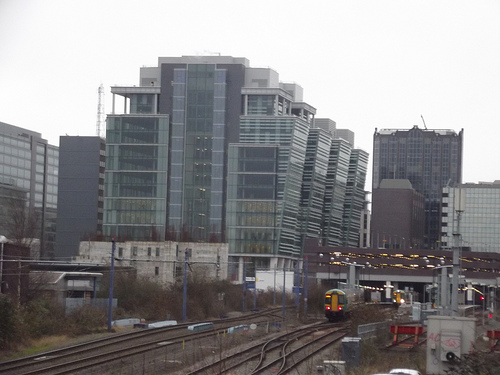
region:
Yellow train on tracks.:
[304, 272, 359, 363]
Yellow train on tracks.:
[384, 278, 438, 355]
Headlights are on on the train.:
[382, 270, 423, 326]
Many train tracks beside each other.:
[166, 317, 241, 369]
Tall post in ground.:
[76, 247, 146, 371]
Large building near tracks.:
[136, 50, 300, 272]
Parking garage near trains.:
[315, 231, 497, 293]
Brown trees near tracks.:
[41, 275, 276, 348]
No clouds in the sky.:
[328, 40, 496, 135]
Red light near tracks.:
[473, 286, 483, 301]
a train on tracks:
[315, 283, 378, 323]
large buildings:
[60, 57, 374, 259]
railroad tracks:
[43, 316, 330, 373]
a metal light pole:
[103, 236, 124, 326]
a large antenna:
[94, 73, 107, 140]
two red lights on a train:
[323, 303, 345, 315]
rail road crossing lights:
[475, 290, 493, 325]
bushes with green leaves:
[115, 275, 286, 320]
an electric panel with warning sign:
[430, 322, 470, 367]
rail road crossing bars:
[350, 280, 388, 300]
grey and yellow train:
[316, 287, 378, 324]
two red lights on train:
[322, 301, 349, 318]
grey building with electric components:
[421, 311, 483, 373]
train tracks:
[34, 313, 366, 370]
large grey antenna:
[87, 78, 110, 141]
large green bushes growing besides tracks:
[6, 257, 120, 351]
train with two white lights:
[381, 283, 441, 320]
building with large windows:
[103, 117, 175, 250]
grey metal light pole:
[92, 228, 134, 338]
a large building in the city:
[102, 46, 364, 252]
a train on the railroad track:
[315, 276, 360, 327]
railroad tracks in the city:
[225, 321, 325, 371]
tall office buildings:
[0, 105, 105, 242]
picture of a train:
[315, 280, 351, 315]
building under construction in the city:
[100, 52, 370, 253]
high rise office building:
[87, 45, 364, 251]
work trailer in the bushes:
[16, 265, 111, 315]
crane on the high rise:
[412, 107, 429, 128]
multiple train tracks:
[140, 308, 321, 373]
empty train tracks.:
[90, 330, 167, 374]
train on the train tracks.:
[321, 284, 365, 314]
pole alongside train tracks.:
[102, 240, 121, 325]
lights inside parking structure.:
[362, 255, 441, 267]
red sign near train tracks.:
[386, 322, 426, 349]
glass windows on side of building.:
[225, 170, 274, 247]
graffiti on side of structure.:
[432, 327, 464, 350]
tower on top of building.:
[97, 80, 104, 140]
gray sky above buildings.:
[343, 44, 430, 97]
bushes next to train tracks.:
[8, 299, 56, 337]